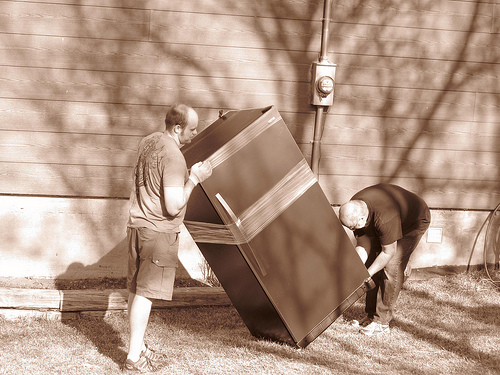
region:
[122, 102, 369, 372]
man in shorts moving a refrigerator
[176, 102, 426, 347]
man in a dark shirt lifting edge of refrigerator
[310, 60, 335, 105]
electric meter on side of house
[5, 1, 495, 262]
shadow of trees against the house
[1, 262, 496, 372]
yard the men are in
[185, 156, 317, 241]
wrapping around the refrigerator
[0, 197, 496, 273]
foundation of the house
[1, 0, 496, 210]
the siding on the house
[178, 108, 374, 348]
the refrigerator being moved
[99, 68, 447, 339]
man trying to carry the refrigerator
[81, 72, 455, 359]
man trying to carry the refrigerator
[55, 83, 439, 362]
man trying to carry the refrigerator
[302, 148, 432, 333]
the man is bending over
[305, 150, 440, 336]
the man is bending over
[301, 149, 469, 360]
the man is bending over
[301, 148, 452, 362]
the man is bending over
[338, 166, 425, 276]
man is bent over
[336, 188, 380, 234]
man has little hair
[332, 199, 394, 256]
man is looking down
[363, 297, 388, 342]
man has on tennis shoes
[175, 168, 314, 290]
fridge has wrapping on it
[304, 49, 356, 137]
some kind of meter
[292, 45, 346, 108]
electricity meter on the wall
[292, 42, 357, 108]
electricity meter on the wall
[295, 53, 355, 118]
electricity meter on the wall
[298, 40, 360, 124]
electricity meter on the wall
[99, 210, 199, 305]
the man is wearing a cargo shorts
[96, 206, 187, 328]
the man is wearing a cargo shorts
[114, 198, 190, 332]
the man is wearing a cargo shorts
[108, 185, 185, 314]
the man is wearing a cargo shorts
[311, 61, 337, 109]
A meter on the side of the house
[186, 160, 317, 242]
Tape around the refridgerator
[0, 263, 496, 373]
Grass beside the house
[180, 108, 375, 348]
A refridgerator by the house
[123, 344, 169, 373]
The man is wearing shoes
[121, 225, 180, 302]
The man is wearing shorts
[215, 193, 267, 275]
A handle on the refridgerator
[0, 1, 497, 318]
A house next to the men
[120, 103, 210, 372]
A man holding the refridgerator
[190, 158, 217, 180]
The right hand of the man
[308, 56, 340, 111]
electricity meter mounted on pole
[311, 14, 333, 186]
vertical pole on wall with electricity meter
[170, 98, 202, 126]
male patterned baldness on head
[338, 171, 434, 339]
stocky man bending over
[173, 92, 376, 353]
refrigerator tilted at angle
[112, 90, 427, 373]
two men moving a refrigerator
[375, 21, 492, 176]
tree branch shadow on wooden panels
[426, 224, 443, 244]
small white electricity outlet access panel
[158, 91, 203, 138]
man on left has short hair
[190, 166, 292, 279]
fridge wrapped in tape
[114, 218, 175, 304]
man on left has shorts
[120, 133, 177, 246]
man has light colored shirt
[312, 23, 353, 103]
meter is on wall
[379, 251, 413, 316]
man on right has pants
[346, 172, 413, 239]
man on right has dark shirt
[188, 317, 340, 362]
shadow cast on the ground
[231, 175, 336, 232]
broad white tape around fridge